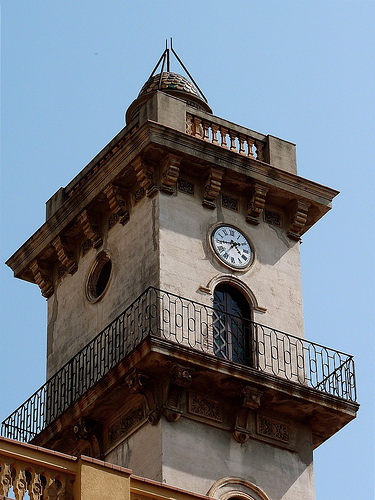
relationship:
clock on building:
[206, 221, 254, 273] [1, 38, 361, 498]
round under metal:
[202, 475, 289, 499] [1, 285, 356, 443]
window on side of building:
[200, 286, 250, 320] [1, 38, 361, 498]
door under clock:
[202, 277, 265, 379] [196, 204, 259, 277]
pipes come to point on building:
[141, 35, 209, 103] [76, 110, 372, 438]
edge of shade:
[162, 461, 212, 485] [157, 414, 309, 479]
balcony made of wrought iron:
[2, 283, 360, 469] [146, 284, 357, 404]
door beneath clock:
[201, 273, 265, 371] [208, 220, 254, 268]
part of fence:
[1, 436, 207, 495] [1, 434, 231, 498]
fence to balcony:
[1, 434, 231, 498] [2, 283, 360, 469]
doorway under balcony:
[206, 473, 287, 498] [2, 283, 360, 469]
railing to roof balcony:
[190, 114, 263, 139] [156, 95, 296, 167]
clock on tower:
[206, 221, 254, 273] [1, 36, 358, 497]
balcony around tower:
[2, 283, 360, 469] [1, 36, 358, 497]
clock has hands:
[209, 221, 254, 272] [218, 237, 244, 253]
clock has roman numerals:
[209, 221, 254, 272] [229, 256, 234, 261]